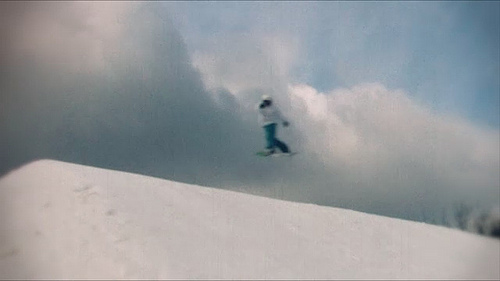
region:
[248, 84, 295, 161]
a person flying through the air.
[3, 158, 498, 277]
a snow covered slope.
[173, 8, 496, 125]
a section of blue sky.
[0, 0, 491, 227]
a snow cloud on a mountain.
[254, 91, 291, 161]
a man dressed for winter.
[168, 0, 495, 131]
a hazy blue sky.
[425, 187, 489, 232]
a section of a hill.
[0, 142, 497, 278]
snow covered ground.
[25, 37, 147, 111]
a section of a snow cloud.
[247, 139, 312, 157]
a snow board.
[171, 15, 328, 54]
this is the sky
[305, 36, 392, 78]
the sky is blue in color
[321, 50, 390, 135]
the sky has some clouds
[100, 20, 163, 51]
the clouds are white in color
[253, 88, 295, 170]
this is a man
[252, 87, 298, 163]
the man is in the air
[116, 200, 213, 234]
this is the ground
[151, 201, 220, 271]
the ground is full of snow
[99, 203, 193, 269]
the snow is white in color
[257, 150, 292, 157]
this is a snowboard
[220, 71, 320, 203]
the man is jumping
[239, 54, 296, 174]
the man is jumping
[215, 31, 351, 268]
the man is jumping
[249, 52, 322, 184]
A man is snowboarding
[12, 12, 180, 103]
The sky is full of snow clouds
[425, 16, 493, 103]
A section of the sky is blue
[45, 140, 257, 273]
Large snow slope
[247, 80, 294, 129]
Man wearing a white hoodie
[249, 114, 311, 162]
Man wearing snow pants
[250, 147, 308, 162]
The snow board is in mid air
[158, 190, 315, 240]
The snow is pure and untouched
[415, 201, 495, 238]
Trees without leaves in the background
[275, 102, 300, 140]
The snow boarders arm is pointing out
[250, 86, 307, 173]
person snowboarding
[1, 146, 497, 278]
mound of snow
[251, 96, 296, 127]
puffy white winter jacket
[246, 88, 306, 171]
person in the air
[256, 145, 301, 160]
thin snowboard in the air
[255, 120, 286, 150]
light blue snow pants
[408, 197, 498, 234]
trees growing out of the snow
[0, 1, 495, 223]
sky covered in clouds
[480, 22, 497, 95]
strip of bright blue sky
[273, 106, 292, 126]
arm extended behind the body